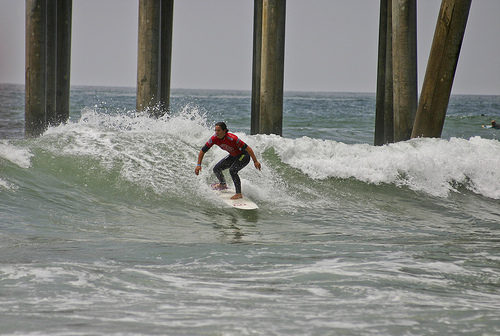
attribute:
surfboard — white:
[205, 187, 264, 216]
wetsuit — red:
[199, 129, 263, 194]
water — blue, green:
[2, 80, 498, 335]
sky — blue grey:
[4, 3, 498, 96]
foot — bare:
[226, 192, 245, 200]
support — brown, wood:
[132, 0, 164, 119]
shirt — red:
[197, 131, 251, 158]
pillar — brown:
[250, 0, 289, 140]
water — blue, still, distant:
[0, 83, 491, 138]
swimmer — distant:
[479, 110, 487, 120]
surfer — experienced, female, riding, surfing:
[196, 121, 261, 200]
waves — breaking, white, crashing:
[34, 108, 498, 195]